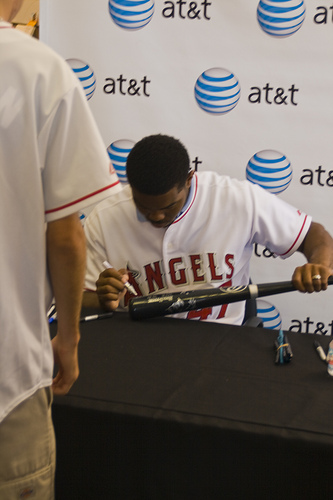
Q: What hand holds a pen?
A: Right.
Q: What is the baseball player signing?
A: A bat.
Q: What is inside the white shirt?
A: A white man's skinny arm.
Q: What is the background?
A: AT&T logos.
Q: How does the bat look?
A: Black.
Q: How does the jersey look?
A: White and red.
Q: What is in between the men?
A: Top of the table.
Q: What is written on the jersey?
A: Angels.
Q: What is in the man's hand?
A: A black bat.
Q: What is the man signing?
A: A baseball bat.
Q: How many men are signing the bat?
A: One.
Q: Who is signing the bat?
A: A baseball player.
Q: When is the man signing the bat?
A: Right now.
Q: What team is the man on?
A: Angels.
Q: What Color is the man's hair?
A: Black.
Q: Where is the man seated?
A: Behind a table.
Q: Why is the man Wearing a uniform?
A: He's a baseball player.